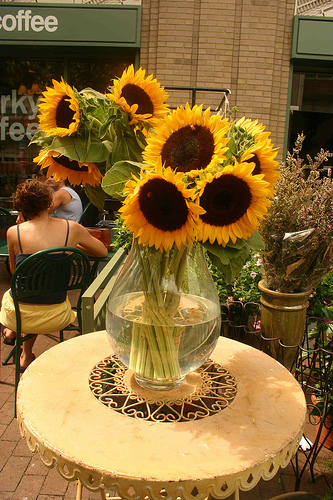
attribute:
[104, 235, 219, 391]
vase — clear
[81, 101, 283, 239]
sunflowers — large, cut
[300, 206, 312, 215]
flower — brown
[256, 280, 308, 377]
vase — tall, brown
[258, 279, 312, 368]
vase — tall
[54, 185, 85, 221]
shirt — blue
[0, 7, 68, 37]
letters — white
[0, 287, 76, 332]
skirt — yellow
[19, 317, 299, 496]
table — metal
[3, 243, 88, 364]
chair — green